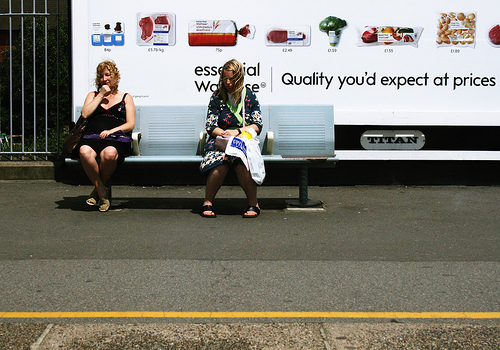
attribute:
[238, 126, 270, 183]
bags — white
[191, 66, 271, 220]
lady — waiting 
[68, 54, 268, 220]
these ladies — strangers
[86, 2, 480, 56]
groceries — an affordable price